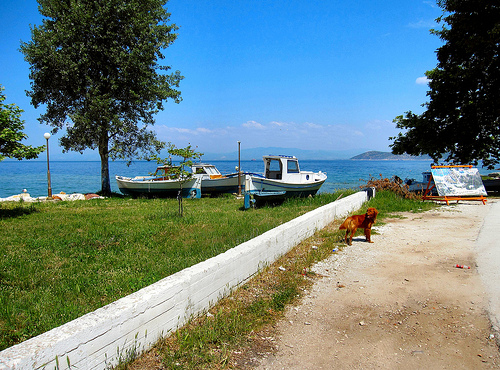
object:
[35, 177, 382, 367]
wall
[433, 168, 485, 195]
sign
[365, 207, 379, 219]
head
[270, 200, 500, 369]
dingy ground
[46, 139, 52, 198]
light pole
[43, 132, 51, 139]
globe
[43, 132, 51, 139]
light bulb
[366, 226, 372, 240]
leg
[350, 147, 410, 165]
wate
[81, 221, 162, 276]
grass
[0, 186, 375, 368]
concrete wall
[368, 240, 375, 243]
feet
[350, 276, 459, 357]
floor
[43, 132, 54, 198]
street light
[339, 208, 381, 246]
body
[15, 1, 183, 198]
tree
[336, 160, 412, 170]
ocean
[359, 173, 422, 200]
branch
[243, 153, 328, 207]
boat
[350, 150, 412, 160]
mountain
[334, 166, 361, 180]
water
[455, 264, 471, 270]
bottle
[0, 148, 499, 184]
water body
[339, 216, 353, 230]
tail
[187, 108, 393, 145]
clouds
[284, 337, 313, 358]
sand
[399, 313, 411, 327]
dirt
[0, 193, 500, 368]
road